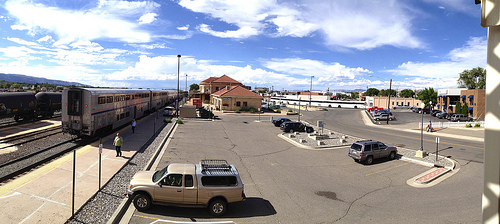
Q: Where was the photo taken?
A: Parking lot.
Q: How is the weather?
A: Sunny and dry.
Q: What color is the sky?
A: Blue.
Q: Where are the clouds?
A: In the sky.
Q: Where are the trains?
A: On the left.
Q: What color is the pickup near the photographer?
A: Beige.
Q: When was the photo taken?
A: Daytime.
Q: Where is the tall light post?
A: Near the building.